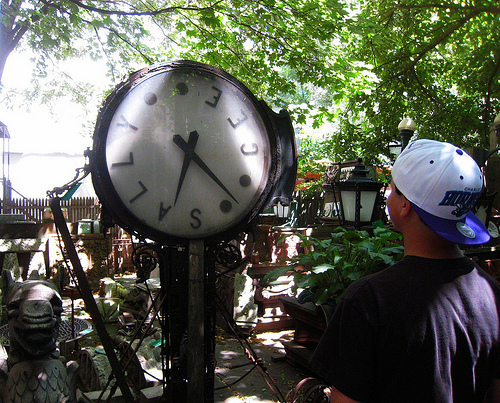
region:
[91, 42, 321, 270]
round black clock with no numbers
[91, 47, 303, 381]
round black clock on black stand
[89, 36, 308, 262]
round black clock with white face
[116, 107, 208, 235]
the word sally written in black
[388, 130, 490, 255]
backwards baseball cap with purple bill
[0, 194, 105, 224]
wooden fence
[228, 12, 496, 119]
green leaves on tree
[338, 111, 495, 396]
boy looking at clock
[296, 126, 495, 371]
boy wearing a dark colored tee shirt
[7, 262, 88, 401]
metal sculpture beside clock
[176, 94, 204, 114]
part of a clock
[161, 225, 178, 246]
bottom of a clock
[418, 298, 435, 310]
part of a shirt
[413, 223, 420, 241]
neck of a boy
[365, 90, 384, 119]
leaves of a tree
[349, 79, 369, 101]
branches of a tree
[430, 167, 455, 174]
part of a snap back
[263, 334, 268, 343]
part of a surface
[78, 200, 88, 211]
part of a fence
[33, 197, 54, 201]
top of a fence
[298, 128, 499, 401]
A young man looking at a clock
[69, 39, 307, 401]
Unusual Metal Clock on pole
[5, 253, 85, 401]
Unusual horse sculpture in the background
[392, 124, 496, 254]
White and blue hat on head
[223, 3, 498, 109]
Green leafy tree branches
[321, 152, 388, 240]
A light fixture in the background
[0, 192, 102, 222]
A wooden picket fence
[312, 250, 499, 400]
A Black T-Shirt on a person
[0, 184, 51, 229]
A wooden Stair Railing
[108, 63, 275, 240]
A white clock face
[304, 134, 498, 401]
man in a black tee shirt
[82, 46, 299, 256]
large black and white clock face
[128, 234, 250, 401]
large metal clock pole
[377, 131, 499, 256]
blue and white base ball cap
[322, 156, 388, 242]
black metal lantern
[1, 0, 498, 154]
large green leafed oak trees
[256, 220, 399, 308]
leafy green bushy plant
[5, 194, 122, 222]
brown wooden picket fence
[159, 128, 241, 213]
pointy black clock hands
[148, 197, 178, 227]
upside down letter A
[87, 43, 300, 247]
clock with white face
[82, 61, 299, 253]
clock with black hands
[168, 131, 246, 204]
black hand on a clock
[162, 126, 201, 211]
black hand on a clock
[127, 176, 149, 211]
black letter on a clock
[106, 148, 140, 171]
black letter on a clock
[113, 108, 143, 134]
black letter on a clock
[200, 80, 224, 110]
black letter on a clock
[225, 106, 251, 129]
black letter on a clock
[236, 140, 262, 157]
black letter on a clock